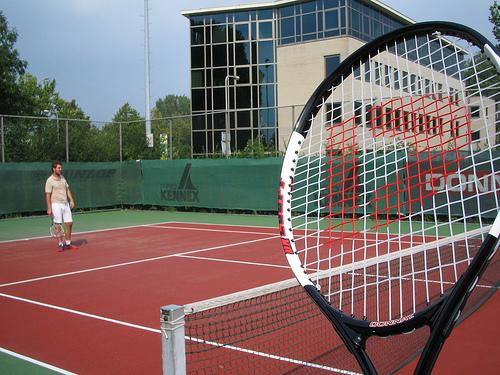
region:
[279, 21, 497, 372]
black tennis racket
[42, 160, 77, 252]
man holding tennis racket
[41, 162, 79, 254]
man waiting for serve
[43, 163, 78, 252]
man wearing white shorts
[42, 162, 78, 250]
man wearing tan short sleeved shirt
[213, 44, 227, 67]
glass window on building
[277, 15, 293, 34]
glass window on building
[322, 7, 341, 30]
glass window on building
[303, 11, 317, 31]
glass window on building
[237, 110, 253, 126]
glass window on building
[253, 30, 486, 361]
Tennis racket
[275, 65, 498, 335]
The racket has a D in the middle of it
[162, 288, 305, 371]
Tennis net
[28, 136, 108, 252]
This man is playing tennis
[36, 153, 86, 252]
The man has a tennis racket in his right hand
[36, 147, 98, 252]
The man is standing on the red part of the court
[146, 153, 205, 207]
Pro Kennex is sponsoring the match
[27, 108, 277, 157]
Wire fence around the court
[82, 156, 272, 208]
Green banners hanging on the fence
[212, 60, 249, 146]
Light post on the other side of the fence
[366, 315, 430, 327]
Red word across the bottom.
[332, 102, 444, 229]
Red letter D in the middle.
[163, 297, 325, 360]
White net across tennis court.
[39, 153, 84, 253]
Man standing on the court.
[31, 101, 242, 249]
Big fence across the court.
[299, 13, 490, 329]
Black white and red tennis racket.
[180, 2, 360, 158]
Side of glass building.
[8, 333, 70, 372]
White stripe on the court.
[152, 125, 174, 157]
White sign in the trees.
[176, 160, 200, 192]
Triangle and black line on court.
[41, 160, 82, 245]
person playing tennis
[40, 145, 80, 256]
person holding tennis racket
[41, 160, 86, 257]
person holding tennis racket with right hand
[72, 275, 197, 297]
red pavement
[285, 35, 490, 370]
tennis racket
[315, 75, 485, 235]
red and white strings of tennis racket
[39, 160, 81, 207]
person is wearing a green shirt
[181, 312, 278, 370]
tennis net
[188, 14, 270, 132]
building with black windows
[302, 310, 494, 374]
partial view of tennis racket handle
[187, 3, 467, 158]
glass building behind tennis court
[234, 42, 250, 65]
glass window on building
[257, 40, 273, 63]
glass window on building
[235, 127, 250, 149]
glass window on building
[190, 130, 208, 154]
glass window on building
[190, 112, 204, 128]
glass window on building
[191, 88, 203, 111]
glass window on building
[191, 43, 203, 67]
glass window on building